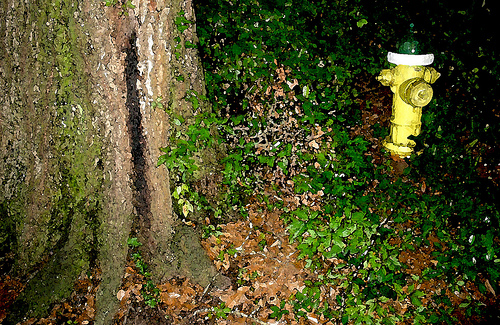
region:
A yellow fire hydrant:
[376, 48, 446, 163]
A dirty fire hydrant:
[381, 52, 429, 165]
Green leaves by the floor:
[285, 192, 382, 284]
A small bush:
[216, 119, 379, 250]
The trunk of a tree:
[5, 65, 231, 210]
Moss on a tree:
[61, 117, 118, 269]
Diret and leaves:
[218, 226, 300, 303]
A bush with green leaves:
[215, 12, 343, 92]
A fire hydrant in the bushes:
[378, 30, 461, 180]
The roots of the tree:
[134, 217, 266, 317]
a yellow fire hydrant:
[374, 18, 448, 161]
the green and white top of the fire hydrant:
[371, 13, 445, 69]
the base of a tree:
[0, 77, 242, 304]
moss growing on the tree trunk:
[23, 181, 97, 278]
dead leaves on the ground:
[208, 201, 339, 301]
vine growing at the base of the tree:
[103, 233, 208, 308]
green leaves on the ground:
[303, 186, 406, 282]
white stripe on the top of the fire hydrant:
[371, 46, 453, 72]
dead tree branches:
[237, 71, 336, 213]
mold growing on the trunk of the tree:
[101, 38, 171, 199]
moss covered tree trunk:
[17, 19, 136, 196]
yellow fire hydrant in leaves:
[373, 44, 449, 160]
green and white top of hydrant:
[381, 22, 445, 67]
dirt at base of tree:
[190, 179, 298, 284]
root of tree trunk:
[79, 250, 132, 322]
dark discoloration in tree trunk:
[119, 29, 148, 194]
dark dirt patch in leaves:
[383, 227, 454, 281]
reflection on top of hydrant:
[402, 40, 426, 62]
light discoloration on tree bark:
[138, 10, 170, 89]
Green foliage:
[290, 5, 367, 300]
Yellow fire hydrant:
[380, 33, 440, 166]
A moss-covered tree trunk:
[0, 2, 242, 303]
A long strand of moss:
[46, 0, 111, 213]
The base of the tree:
[1, 165, 240, 320]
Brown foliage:
[202, 202, 297, 324]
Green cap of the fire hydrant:
[386, 22, 431, 50]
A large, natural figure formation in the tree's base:
[122, 30, 155, 255]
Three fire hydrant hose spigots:
[372, 62, 442, 104]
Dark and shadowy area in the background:
[364, 0, 499, 42]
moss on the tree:
[24, 9, 134, 307]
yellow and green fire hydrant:
[369, 35, 442, 165]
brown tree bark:
[20, 3, 248, 287]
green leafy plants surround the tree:
[277, 145, 416, 300]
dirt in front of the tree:
[124, 302, 171, 322]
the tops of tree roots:
[57, 228, 282, 318]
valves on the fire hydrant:
[374, 64, 444, 109]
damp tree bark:
[112, 30, 159, 245]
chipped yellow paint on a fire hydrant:
[385, 67, 423, 157]